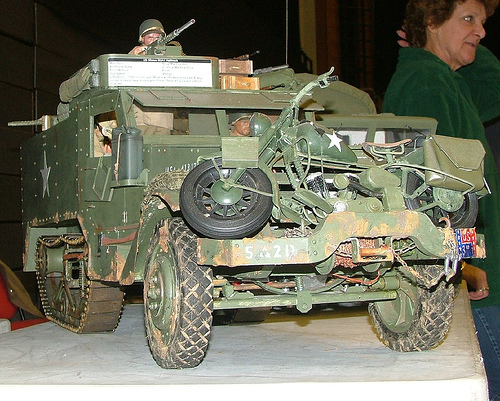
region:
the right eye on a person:
[451, 10, 481, 27]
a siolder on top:
[119, 15, 171, 57]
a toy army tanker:
[3, 0, 490, 395]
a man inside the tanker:
[228, 108, 270, 136]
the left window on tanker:
[78, 110, 135, 170]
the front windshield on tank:
[118, 89, 320, 150]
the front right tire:
[123, 233, 227, 365]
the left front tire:
[371, 251, 461, 363]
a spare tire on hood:
[170, 135, 274, 243]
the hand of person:
[451, 260, 494, 320]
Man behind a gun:
[128, 17, 185, 63]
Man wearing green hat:
[137, 15, 173, 50]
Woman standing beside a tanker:
[383, 2, 498, 394]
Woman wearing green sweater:
[385, 3, 499, 298]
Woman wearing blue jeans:
[468, 280, 498, 400]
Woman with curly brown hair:
[403, 0, 498, 70]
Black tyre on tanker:
[179, 159, 272, 237]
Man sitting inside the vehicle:
[231, 109, 261, 142]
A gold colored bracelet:
[455, 259, 470, 274]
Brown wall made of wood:
[0, 0, 310, 271]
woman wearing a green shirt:
[381, 0, 499, 134]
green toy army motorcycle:
[181, 64, 495, 261]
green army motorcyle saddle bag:
[407, 119, 498, 254]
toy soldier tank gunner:
[98, 3, 233, 91]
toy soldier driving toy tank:
[103, 100, 352, 379]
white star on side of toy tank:
[15, 100, 127, 340]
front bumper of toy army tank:
[192, 198, 489, 293]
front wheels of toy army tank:
[133, 212, 467, 374]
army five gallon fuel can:
[104, 123, 154, 189]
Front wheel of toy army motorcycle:
[171, 155, 285, 237]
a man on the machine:
[118, 15, 198, 59]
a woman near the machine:
[387, 15, 496, 115]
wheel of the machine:
[106, 224, 252, 393]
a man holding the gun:
[129, 13, 251, 71]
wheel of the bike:
[166, 140, 483, 247]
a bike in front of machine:
[167, 38, 493, 252]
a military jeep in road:
[21, 34, 466, 391]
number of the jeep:
[227, 224, 327, 287]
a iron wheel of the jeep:
[38, 243, 148, 343]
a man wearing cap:
[126, 3, 176, 35]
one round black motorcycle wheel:
[176, 153, 275, 235]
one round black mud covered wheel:
[139, 215, 212, 368]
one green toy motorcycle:
[178, 69, 483, 235]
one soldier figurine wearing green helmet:
[128, 12, 202, 63]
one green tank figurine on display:
[16, 12, 486, 372]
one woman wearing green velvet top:
[388, 3, 493, 128]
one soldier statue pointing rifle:
[126, 17, 202, 54]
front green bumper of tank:
[196, 217, 493, 269]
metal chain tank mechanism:
[30, 229, 127, 336]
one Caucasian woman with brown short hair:
[402, 2, 486, 69]